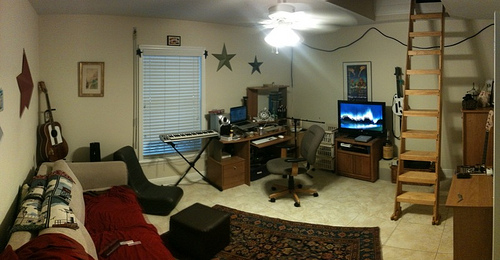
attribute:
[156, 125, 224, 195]
piano — gray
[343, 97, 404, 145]
television — turned on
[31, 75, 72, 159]
guitar — dark wooden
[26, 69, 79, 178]
guitar — brown , white 